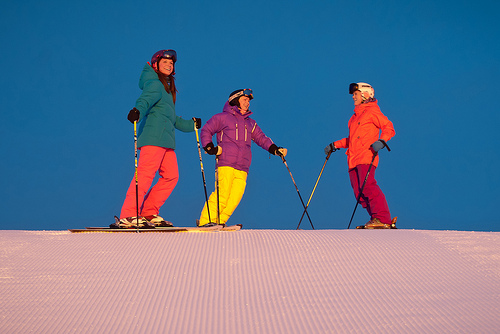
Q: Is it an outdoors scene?
A: Yes, it is outdoors.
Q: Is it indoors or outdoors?
A: It is outdoors.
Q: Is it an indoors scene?
A: No, it is outdoors.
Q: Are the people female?
A: Yes, all the people are female.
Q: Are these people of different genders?
A: No, all the people are female.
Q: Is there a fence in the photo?
A: No, there are no fences.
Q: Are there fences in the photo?
A: No, there are no fences.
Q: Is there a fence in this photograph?
A: No, there are no fences.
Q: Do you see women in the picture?
A: Yes, there is a woman.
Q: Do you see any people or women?
A: Yes, there is a woman.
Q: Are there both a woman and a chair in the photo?
A: No, there is a woman but no chairs.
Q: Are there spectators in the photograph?
A: No, there are no spectators.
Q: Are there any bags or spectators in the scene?
A: No, there are no spectators or bags.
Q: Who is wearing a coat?
A: The woman is wearing a coat.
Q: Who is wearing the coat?
A: The woman is wearing a coat.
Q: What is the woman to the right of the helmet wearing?
A: The woman is wearing a coat.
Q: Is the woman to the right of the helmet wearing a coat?
A: Yes, the woman is wearing a coat.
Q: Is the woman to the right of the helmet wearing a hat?
A: No, the woman is wearing a coat.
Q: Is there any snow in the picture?
A: Yes, there is snow.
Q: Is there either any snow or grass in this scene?
A: Yes, there is snow.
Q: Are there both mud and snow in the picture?
A: No, there is snow but no mud.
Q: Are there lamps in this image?
A: No, there are no lamps.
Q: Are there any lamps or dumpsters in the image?
A: No, there are no lamps or dumpsters.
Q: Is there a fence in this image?
A: No, there are no fences.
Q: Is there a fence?
A: No, there are no fences.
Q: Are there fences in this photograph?
A: No, there are no fences.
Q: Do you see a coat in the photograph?
A: Yes, there is a coat.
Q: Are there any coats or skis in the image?
A: Yes, there is a coat.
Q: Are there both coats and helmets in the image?
A: Yes, there are both a coat and a helmet.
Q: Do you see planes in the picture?
A: No, there are no planes.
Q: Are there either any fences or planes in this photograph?
A: No, there are no planes or fences.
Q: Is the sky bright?
A: Yes, the sky is bright.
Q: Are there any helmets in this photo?
A: Yes, there is a helmet.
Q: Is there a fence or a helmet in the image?
A: Yes, there is a helmet.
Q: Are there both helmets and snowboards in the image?
A: No, there is a helmet but no snowboards.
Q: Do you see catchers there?
A: No, there are no catchers.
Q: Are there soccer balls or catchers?
A: No, there are no catchers or soccer balls.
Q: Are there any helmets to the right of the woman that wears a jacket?
A: Yes, there is a helmet to the right of the woman.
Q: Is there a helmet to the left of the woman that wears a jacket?
A: No, the helmet is to the right of the woman.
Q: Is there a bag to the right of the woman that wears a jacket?
A: No, there is a helmet to the right of the woman.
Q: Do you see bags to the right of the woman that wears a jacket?
A: No, there is a helmet to the right of the woman.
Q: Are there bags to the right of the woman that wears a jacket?
A: No, there is a helmet to the right of the woman.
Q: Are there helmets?
A: Yes, there is a helmet.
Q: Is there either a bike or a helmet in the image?
A: Yes, there is a helmet.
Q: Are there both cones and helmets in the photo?
A: No, there is a helmet but no cones.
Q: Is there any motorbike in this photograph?
A: No, there are no motorcycles.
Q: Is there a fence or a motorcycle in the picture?
A: No, there are no motorcycles or fences.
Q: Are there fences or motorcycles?
A: No, there are no motorcycles or fences.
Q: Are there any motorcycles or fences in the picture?
A: No, there are no motorcycles or fences.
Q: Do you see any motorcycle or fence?
A: No, there are no motorcycles or fences.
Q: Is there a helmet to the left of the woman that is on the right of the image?
A: Yes, there is a helmet to the left of the woman.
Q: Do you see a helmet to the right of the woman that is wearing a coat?
A: No, the helmet is to the left of the woman.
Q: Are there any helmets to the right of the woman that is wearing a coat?
A: No, the helmet is to the left of the woman.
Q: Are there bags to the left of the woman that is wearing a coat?
A: No, there is a helmet to the left of the woman.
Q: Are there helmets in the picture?
A: Yes, there is a helmet.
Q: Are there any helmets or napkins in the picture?
A: Yes, there is a helmet.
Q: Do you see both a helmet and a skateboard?
A: No, there is a helmet but no skateboards.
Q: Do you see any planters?
A: No, there are no planters.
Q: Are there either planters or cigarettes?
A: No, there are no planters or cigarettes.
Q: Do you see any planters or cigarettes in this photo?
A: No, there are no planters or cigarettes.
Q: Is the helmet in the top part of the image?
A: Yes, the helmet is in the top of the image.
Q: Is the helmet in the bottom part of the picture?
A: No, the helmet is in the top of the image.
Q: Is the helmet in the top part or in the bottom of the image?
A: The helmet is in the top of the image.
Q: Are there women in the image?
A: Yes, there is a woman.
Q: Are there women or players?
A: Yes, there is a woman.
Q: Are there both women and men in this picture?
A: No, there is a woman but no men.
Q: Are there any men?
A: No, there are no men.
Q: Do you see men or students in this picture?
A: No, there are no men or students.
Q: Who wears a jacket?
A: The woman wears a jacket.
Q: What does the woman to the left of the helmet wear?
A: The woman wears a jacket.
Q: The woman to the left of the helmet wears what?
A: The woman wears a jacket.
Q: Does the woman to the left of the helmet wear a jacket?
A: Yes, the woman wears a jacket.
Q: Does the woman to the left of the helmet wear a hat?
A: No, the woman wears a jacket.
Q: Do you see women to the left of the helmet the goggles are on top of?
A: Yes, there is a woman to the left of the helmet.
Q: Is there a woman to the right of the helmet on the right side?
A: No, the woman is to the left of the helmet.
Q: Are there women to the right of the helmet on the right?
A: No, the woman is to the left of the helmet.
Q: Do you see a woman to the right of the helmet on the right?
A: No, the woman is to the left of the helmet.